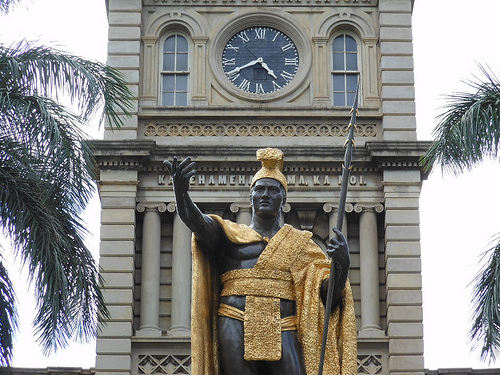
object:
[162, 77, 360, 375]
statue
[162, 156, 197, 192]
hand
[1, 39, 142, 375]
tree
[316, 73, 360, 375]
weapon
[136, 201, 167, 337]
columns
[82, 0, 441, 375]
building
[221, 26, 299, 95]
clock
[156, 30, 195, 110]
window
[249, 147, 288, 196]
head band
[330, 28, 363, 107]
window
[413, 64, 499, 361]
tree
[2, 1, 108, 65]
sky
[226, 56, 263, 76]
hand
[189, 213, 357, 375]
robe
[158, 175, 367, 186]
words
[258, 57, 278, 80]
hand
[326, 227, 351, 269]
hand